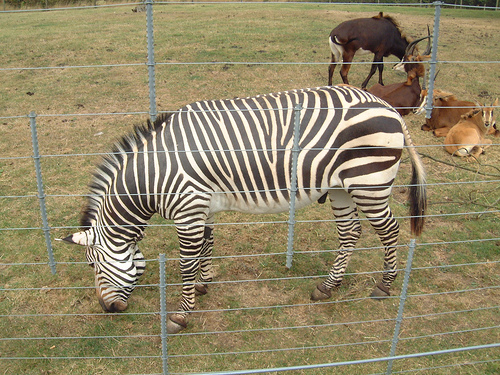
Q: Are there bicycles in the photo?
A: No, there are no bicycles.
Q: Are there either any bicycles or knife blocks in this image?
A: No, there are no bicycles or knife blocks.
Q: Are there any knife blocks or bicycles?
A: No, there are no bicycles or knife blocks.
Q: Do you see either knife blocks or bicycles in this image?
A: No, there are no bicycles or knife blocks.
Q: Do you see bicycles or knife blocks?
A: No, there are no bicycles or knife blocks.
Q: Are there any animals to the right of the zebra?
A: Yes, there is an animal to the right of the zebra.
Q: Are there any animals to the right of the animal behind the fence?
A: Yes, there is an animal to the right of the zebra.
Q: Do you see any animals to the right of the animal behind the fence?
A: Yes, there is an animal to the right of the zebra.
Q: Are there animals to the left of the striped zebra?
A: No, the animal is to the right of the zebra.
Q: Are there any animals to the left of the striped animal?
A: No, the animal is to the right of the zebra.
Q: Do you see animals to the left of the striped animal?
A: No, the animal is to the right of the zebra.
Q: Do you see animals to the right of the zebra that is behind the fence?
A: Yes, there is an animal to the right of the zebra.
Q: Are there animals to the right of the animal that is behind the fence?
A: Yes, there is an animal to the right of the zebra.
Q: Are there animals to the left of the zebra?
A: No, the animal is to the right of the zebra.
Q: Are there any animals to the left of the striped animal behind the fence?
A: No, the animal is to the right of the zebra.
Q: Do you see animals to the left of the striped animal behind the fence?
A: No, the animal is to the right of the zebra.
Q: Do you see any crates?
A: No, there are no crates.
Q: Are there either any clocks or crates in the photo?
A: No, there are no crates or clocks.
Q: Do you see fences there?
A: Yes, there is a fence.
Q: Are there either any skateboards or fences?
A: Yes, there is a fence.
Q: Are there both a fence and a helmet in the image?
A: No, there is a fence but no helmets.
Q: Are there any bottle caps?
A: No, there are no bottle caps.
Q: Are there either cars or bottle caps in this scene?
A: No, there are no bottle caps or cars.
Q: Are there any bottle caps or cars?
A: No, there are no bottle caps or cars.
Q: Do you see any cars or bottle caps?
A: No, there are no bottle caps or cars.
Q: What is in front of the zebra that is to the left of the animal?
A: The fence is in front of the zebra.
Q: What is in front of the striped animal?
A: The fence is in front of the zebra.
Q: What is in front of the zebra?
A: The fence is in front of the zebra.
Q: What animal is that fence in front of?
A: The fence is in front of the zebra.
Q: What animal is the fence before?
A: The fence is in front of the zebra.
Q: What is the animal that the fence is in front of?
A: The animal is a zebra.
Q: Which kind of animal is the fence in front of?
A: The fence is in front of the zebra.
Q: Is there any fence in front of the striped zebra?
A: Yes, there is a fence in front of the zebra.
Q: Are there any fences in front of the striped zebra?
A: Yes, there is a fence in front of the zebra.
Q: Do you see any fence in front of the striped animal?
A: Yes, there is a fence in front of the zebra.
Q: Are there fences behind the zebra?
A: No, the fence is in front of the zebra.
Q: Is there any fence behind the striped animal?
A: No, the fence is in front of the zebra.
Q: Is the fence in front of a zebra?
A: Yes, the fence is in front of a zebra.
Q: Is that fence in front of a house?
A: No, the fence is in front of a zebra.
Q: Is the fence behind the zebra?
A: No, the fence is in front of the zebra.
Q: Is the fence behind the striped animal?
A: No, the fence is in front of the zebra.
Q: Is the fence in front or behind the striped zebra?
A: The fence is in front of the zebra.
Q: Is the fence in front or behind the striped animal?
A: The fence is in front of the zebra.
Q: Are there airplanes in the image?
A: No, there are no airplanes.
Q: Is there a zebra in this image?
A: Yes, there is a zebra.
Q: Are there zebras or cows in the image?
A: Yes, there is a zebra.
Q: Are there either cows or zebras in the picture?
A: Yes, there is a zebra.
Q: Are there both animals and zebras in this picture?
A: Yes, there are both a zebra and an animal.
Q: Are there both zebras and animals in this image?
A: Yes, there are both a zebra and an animal.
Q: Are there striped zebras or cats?
A: Yes, there is a striped zebra.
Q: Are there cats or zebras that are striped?
A: Yes, the zebra is striped.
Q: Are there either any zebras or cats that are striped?
A: Yes, the zebra is striped.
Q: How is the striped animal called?
A: The animal is a zebra.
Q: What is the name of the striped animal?
A: The animal is a zebra.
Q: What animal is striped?
A: The animal is a zebra.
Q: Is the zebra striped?
A: Yes, the zebra is striped.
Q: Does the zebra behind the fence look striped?
A: Yes, the zebra is striped.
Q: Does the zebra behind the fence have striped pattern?
A: Yes, the zebra is striped.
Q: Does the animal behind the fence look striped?
A: Yes, the zebra is striped.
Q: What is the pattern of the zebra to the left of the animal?
A: The zebra is striped.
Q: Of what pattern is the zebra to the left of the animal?
A: The zebra is striped.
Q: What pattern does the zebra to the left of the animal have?
A: The zebra has striped pattern.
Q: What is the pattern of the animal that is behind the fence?
A: The zebra is striped.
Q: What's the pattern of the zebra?
A: The zebra is striped.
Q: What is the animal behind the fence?
A: The animal is a zebra.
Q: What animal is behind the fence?
A: The animal is a zebra.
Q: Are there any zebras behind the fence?
A: Yes, there is a zebra behind the fence.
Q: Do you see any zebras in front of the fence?
A: No, the zebra is behind the fence.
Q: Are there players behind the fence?
A: No, there is a zebra behind the fence.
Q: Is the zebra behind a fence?
A: Yes, the zebra is behind a fence.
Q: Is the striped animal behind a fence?
A: Yes, the zebra is behind a fence.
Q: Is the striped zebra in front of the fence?
A: No, the zebra is behind the fence.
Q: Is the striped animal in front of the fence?
A: No, the zebra is behind the fence.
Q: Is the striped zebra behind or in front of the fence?
A: The zebra is behind the fence.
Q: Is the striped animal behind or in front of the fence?
A: The zebra is behind the fence.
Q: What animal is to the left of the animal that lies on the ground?
A: The animal is a zebra.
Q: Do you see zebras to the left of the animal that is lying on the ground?
A: Yes, there is a zebra to the left of the animal.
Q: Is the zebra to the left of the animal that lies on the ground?
A: Yes, the zebra is to the left of the animal.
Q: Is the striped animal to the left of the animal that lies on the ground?
A: Yes, the zebra is to the left of the animal.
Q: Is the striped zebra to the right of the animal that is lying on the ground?
A: No, the zebra is to the left of the animal.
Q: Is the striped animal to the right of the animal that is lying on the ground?
A: No, the zebra is to the left of the animal.